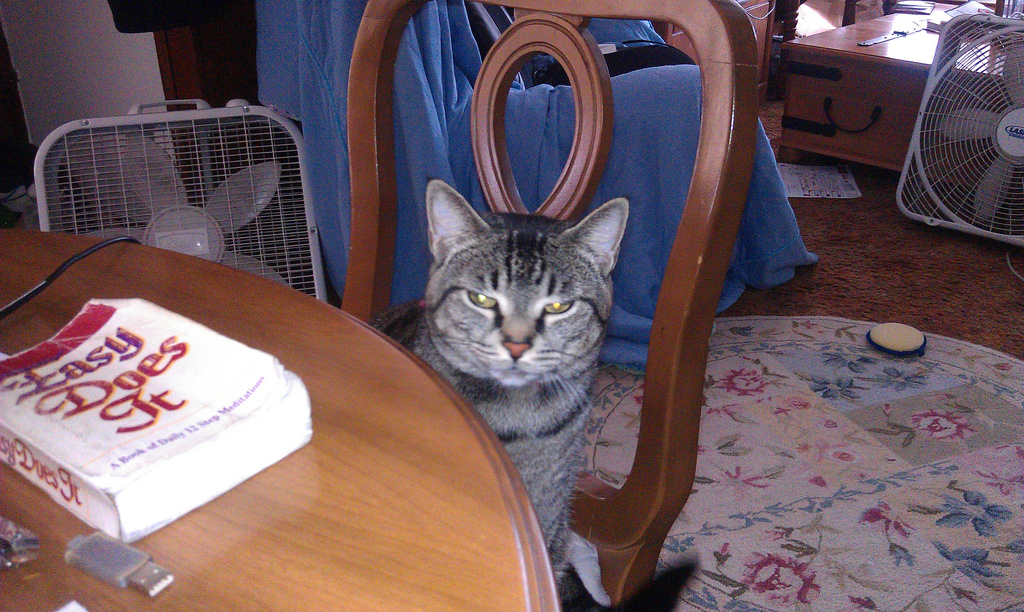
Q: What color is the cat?
A: Black and Grey.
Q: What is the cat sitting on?
A: A wooden chair.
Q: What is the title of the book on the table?
A: Easy Does it.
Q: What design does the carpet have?
A: A Floral design.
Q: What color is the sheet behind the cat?
A: Blue.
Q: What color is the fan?
A: White.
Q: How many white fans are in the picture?
A: Two.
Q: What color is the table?
A: Brown.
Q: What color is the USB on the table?
A: Grey.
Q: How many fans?
A: Two.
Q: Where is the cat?
A: In chair.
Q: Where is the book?
A: On table.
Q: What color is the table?
A: Brown.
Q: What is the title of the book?
A: Easy Does It.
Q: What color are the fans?
A: White.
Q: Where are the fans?
A: On floor.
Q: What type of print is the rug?
A: Floral.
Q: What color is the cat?
A: Gray and black.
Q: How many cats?
A: One.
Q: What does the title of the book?
A: Easy Does It.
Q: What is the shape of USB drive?
A: Rectangular.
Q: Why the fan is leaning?
A: So it won't fall.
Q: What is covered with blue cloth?
A: Chair.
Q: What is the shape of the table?
A: Round.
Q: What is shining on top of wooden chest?
A: Sun.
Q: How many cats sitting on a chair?
A: One.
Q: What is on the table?
A: Book.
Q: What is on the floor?
A: A fan.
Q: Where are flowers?
A: On carpet.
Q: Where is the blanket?
A: On sofa.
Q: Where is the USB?
A: On table.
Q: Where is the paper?
A: On floor.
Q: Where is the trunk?
A: On floor.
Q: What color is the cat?
A: Gray.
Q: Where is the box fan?
A: On floor.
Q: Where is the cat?
A: On chair.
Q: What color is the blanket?
A: Blue.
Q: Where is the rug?
A: On floor.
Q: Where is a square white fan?
A: Floor behind chair.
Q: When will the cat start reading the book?
A: Never.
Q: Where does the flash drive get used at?
A: Computer.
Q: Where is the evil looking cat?
A: On chair.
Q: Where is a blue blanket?
A: Covering chair.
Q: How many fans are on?
A: 0.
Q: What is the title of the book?
A: Easy Does It.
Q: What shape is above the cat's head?
A: Oval.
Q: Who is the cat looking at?
A: Person taking picture.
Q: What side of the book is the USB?
A: Left.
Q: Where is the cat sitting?
A: In the chair.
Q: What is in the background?
A: A fan.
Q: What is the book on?
A: The table.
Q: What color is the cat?
A: Gray and black.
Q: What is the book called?
A: Easy does it.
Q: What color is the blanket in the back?
A: Blue.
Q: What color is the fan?
A: White.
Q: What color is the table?
A: Brown.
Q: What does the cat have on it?
A: Stripes.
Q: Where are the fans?
A: The floor.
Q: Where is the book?
A: The table.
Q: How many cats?
A: One.